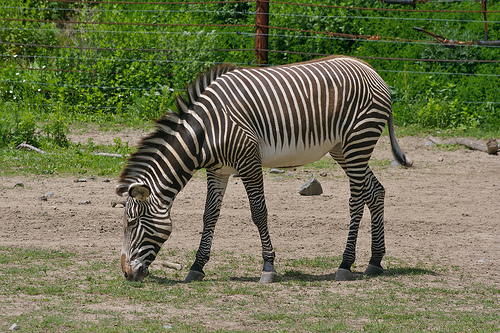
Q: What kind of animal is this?
A: Zebra.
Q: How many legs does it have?
A: 4.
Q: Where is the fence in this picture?
A: Behind the zebra.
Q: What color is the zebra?
A: Black and white.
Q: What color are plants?
A: Green.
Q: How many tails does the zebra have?
A: One.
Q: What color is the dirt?
A: Brown.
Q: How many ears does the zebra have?
A: Two.